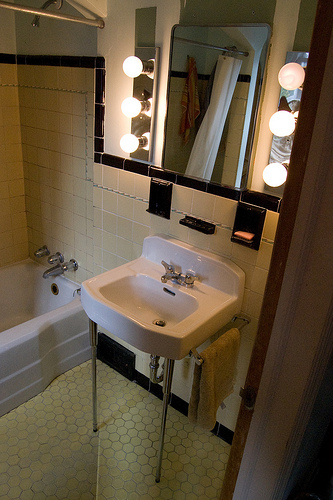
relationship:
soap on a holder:
[236, 228, 254, 241] [239, 203, 262, 245]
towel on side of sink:
[208, 335, 235, 405] [134, 234, 222, 335]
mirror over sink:
[171, 21, 250, 187] [134, 234, 222, 335]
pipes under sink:
[143, 353, 163, 383] [134, 234, 222, 335]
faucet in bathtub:
[45, 264, 63, 277] [6, 267, 83, 375]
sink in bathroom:
[134, 234, 222, 335] [12, 2, 330, 484]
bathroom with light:
[12, 2, 330, 484] [121, 98, 140, 114]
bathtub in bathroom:
[6, 267, 83, 375] [12, 2, 330, 484]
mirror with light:
[171, 21, 250, 187] [121, 98, 140, 114]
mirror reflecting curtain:
[171, 21, 250, 187] [211, 53, 241, 171]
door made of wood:
[282, 208, 332, 412] [299, 126, 331, 243]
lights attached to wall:
[123, 56, 143, 77] [133, 12, 160, 44]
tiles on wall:
[106, 190, 118, 215] [101, 188, 120, 214]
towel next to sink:
[208, 335, 235, 405] [134, 234, 222, 335]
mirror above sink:
[171, 21, 250, 187] [134, 234, 222, 335]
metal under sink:
[143, 353, 163, 383] [134, 234, 222, 335]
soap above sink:
[236, 228, 254, 241] [134, 234, 222, 335]